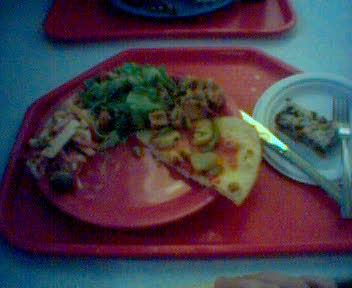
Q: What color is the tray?
A: Red.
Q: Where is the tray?
A: On the table.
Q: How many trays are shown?
A: Two.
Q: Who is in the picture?
A: No one.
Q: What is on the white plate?
A: Fork and knife.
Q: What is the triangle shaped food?
A: Pizza.